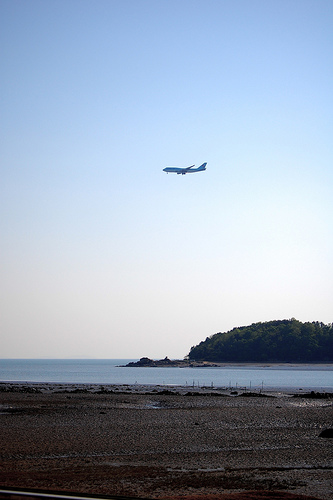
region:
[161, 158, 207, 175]
an airliner flying in the sky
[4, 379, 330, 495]
a wet beach by the sea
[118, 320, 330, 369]
a small peninsula in the distance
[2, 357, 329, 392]
the sea by the beach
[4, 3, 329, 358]
the clear blue sky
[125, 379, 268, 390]
poles by the waterside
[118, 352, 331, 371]
a rocky beach on the peninsula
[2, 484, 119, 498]
a roadway by the beach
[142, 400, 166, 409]
a water puddle on the beach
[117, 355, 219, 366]
rocks in the distance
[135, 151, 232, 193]
commercial airliner in flight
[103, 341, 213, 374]
point of land surrounded by water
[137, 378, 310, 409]
shore with seaweed on it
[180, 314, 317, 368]
trees on land in background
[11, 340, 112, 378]
blue water and the horizon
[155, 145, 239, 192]
an airplane in the sky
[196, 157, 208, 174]
the tail of a commercial airplane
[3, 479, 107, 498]
white line on paved surface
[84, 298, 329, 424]
an inlet of water between land masses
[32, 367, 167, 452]
sand and grass on a beach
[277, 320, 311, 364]
There is a dark green mass of trees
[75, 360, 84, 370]
There is a bright, blue patch of water here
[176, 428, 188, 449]
There is a light-colored sand that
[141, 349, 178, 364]
There is a peninsula that is visible here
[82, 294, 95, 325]
There is a sky that is very light in color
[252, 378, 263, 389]
There are large twigs that are visible here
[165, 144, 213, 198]
There is a large plane that is visible here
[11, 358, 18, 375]
The water here looks as though it might be dirty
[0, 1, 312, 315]
A blue sky with an airplane.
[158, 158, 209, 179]
An airplane in the sky.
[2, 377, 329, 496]
A rocky beach.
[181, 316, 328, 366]
Trees along a shoreline.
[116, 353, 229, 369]
An island in the ocean.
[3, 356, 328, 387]
Blue water of the ocean.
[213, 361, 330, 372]
A beach shoreline.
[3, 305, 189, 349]
A white sky over the beach.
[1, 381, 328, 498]
Brown sand near the ocean.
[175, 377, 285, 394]
Fence near the water's edge.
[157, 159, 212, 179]
Plane flying in the sky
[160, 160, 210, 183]
Dark silhouette of plane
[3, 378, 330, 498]
Dark sandy beach area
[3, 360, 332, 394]
large body of water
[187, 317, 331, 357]
Large amount of forest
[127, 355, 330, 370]
Beach across the ocean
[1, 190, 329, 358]
White section of the sky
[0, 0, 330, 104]
Dark blue section of the sky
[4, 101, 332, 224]
Blue to white gradient in the sky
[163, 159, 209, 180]
Airplane in blue sky